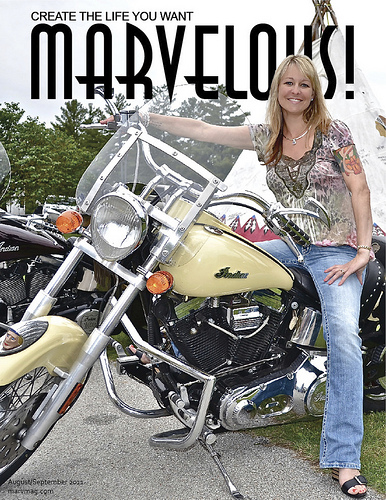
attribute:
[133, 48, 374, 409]
lady — posing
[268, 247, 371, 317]
seat — leather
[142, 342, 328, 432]
foot rest — chrome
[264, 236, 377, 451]
jean — blue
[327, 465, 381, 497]
sandle — black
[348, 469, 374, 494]
nail — polish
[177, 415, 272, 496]
stand — kick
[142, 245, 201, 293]
light — motorcycle, orange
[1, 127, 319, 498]
bike — sitting, standing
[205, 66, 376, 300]
woman — sitting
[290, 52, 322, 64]
hair — blonde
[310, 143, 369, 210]
tattoo — green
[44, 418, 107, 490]
asphalt — gray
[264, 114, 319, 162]
necklace — silver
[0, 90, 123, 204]
tree — green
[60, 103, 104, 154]
leave — green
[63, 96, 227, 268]
windshield — clear